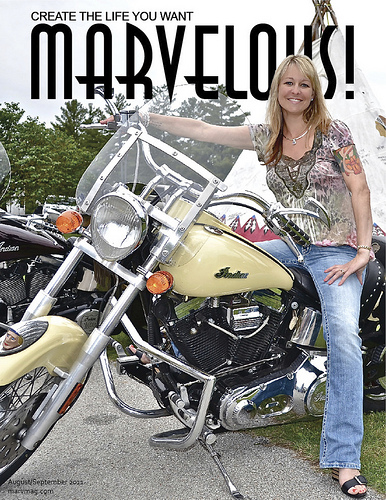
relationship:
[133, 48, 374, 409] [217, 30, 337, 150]
lady in open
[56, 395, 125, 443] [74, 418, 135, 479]
stain in concrete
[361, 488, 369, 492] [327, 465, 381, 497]
toes in sandle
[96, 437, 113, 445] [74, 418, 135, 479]
gravel on ground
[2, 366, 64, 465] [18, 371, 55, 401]
tire has spokes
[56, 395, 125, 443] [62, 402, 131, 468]
stain on pavement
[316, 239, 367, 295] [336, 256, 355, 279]
finger has ring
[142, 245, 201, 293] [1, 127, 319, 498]
light on bike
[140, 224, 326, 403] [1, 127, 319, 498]
engine of bike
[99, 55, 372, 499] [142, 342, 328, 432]
lady with foot rest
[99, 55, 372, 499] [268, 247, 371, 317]
lady has hand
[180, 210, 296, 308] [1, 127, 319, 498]
body of motorcycle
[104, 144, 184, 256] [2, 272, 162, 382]
head on fender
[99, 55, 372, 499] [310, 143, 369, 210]
lady has tattoo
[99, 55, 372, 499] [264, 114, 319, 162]
lady has jewelry